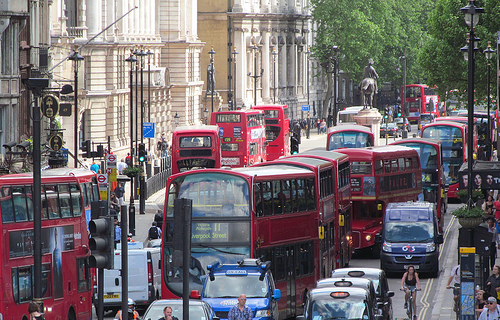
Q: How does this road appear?
A: Busy.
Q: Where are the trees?
A: By buildings.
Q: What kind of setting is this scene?
A: CIty scene.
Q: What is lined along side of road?
A: Buildings.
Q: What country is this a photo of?
A: England.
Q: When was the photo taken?
A: In the daytime.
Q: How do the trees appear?
A: Green and lush.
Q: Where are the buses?
A: On the street.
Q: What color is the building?
A: White.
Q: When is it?
A: Day time.